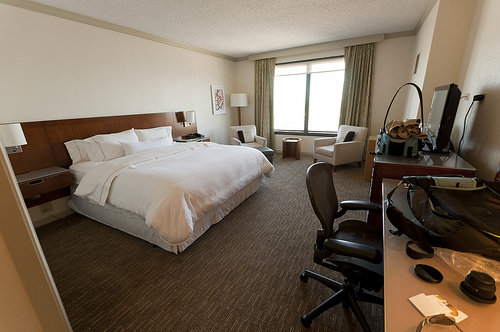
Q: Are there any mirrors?
A: No, there are no mirrors.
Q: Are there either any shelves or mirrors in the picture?
A: No, there are no mirrors or shelves.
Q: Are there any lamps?
A: Yes, there is a lamp.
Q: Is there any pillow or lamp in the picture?
A: Yes, there is a lamp.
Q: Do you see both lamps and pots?
A: No, there is a lamp but no pots.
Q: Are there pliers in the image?
A: No, there are no pliers.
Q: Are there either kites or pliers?
A: No, there are no pliers or kites.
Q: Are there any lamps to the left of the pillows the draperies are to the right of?
A: Yes, there is a lamp to the left of the pillows.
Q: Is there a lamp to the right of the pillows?
A: No, the lamp is to the left of the pillows.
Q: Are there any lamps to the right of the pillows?
A: No, the lamp is to the left of the pillows.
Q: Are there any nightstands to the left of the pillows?
A: No, there is a lamp to the left of the pillows.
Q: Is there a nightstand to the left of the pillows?
A: No, there is a lamp to the left of the pillows.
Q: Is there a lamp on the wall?
A: Yes, there is a lamp on the wall.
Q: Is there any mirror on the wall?
A: No, there is a lamp on the wall.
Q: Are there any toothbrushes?
A: No, there are no toothbrushes.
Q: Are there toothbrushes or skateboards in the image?
A: No, there are no toothbrushes or skateboards.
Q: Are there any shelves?
A: No, there are no shelves.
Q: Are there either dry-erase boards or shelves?
A: No, there are no shelves or dry-erase boards.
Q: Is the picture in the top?
A: Yes, the picture is in the top of the image.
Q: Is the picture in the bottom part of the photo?
A: No, the picture is in the top of the image.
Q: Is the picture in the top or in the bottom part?
A: The picture is in the top of the image.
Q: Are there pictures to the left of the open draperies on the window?
A: Yes, there is a picture to the left of the drapes.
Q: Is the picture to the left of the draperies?
A: Yes, the picture is to the left of the draperies.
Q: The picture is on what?
A: The picture is on the wall.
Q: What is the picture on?
A: The picture is on the wall.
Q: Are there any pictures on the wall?
A: Yes, there is a picture on the wall.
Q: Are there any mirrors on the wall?
A: No, there is a picture on the wall.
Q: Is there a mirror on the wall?
A: No, there is a picture on the wall.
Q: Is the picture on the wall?
A: Yes, the picture is on the wall.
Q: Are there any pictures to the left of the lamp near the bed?
A: Yes, there is a picture to the left of the lamp.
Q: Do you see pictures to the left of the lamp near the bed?
A: Yes, there is a picture to the left of the lamp.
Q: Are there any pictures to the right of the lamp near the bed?
A: No, the picture is to the left of the lamp.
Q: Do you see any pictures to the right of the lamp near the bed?
A: No, the picture is to the left of the lamp.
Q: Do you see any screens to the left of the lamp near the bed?
A: No, there is a picture to the left of the lamp.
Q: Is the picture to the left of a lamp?
A: Yes, the picture is to the left of a lamp.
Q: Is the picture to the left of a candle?
A: No, the picture is to the left of a lamp.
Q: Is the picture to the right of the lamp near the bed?
A: No, the picture is to the left of the lamp.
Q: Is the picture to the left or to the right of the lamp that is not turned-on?
A: The picture is to the left of the lamp.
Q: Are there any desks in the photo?
A: Yes, there is a desk.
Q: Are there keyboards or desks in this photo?
A: Yes, there is a desk.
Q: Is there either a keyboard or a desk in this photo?
A: Yes, there is a desk.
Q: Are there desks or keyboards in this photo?
A: Yes, there is a desk.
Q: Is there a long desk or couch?
A: Yes, there is a long desk.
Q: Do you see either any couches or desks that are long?
A: Yes, the desk is long.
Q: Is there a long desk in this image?
A: Yes, there is a long desk.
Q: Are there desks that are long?
A: Yes, there is a desk that is long.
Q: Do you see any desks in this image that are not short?
A: Yes, there is a long desk.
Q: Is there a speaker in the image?
A: No, there are no speakers.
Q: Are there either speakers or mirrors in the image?
A: No, there are no speakers or mirrors.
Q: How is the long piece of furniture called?
A: The piece of furniture is a desk.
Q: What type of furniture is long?
A: The furniture is a desk.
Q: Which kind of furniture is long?
A: The furniture is a desk.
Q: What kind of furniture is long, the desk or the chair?
A: The desk is long.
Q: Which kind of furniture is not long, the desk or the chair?
A: The chair is not long.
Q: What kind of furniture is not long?
A: The furniture is a chair.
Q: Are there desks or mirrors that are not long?
A: No, there is a desk but it is long.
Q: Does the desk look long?
A: Yes, the desk is long.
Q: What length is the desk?
A: The desk is long.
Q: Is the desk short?
A: No, the desk is long.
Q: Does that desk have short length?
A: No, the desk is long.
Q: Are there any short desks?
A: No, there is a desk but it is long.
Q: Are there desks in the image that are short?
A: No, there is a desk but it is long.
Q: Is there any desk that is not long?
A: No, there is a desk but it is long.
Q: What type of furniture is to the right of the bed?
A: The piece of furniture is a desk.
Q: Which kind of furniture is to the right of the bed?
A: The piece of furniture is a desk.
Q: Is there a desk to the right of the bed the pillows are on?
A: Yes, there is a desk to the right of the bed.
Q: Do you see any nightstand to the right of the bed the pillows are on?
A: No, there is a desk to the right of the bed.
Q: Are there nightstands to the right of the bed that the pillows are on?
A: No, there is a desk to the right of the bed.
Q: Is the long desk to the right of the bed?
A: Yes, the desk is to the right of the bed.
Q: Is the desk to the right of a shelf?
A: No, the desk is to the right of the bed.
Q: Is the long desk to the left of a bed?
A: No, the desk is to the right of a bed.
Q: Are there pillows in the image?
A: Yes, there are pillows.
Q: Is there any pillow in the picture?
A: Yes, there are pillows.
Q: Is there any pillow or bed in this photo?
A: Yes, there are pillows.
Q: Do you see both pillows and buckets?
A: No, there are pillows but no buckets.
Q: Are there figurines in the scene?
A: No, there are no figurines.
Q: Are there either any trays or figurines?
A: No, there are no figurines or trays.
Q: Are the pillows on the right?
A: No, the pillows are on the left of the image.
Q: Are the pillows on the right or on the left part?
A: The pillows are on the left of the image.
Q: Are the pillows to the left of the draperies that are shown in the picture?
A: Yes, the pillows are to the left of the draperies.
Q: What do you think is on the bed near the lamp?
A: The pillows are on the bed.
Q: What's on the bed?
A: The pillows are on the bed.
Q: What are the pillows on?
A: The pillows are on the bed.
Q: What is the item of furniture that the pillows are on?
A: The piece of furniture is a bed.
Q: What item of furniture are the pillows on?
A: The pillows are on the bed.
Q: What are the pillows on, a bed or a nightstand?
A: The pillows are on a bed.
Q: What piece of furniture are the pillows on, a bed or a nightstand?
A: The pillows are on a bed.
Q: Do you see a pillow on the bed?
A: Yes, there are pillows on the bed.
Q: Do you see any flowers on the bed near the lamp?
A: No, there are pillows on the bed.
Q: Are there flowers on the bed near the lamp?
A: No, there are pillows on the bed.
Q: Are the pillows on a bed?
A: Yes, the pillows are on a bed.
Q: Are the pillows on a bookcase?
A: No, the pillows are on a bed.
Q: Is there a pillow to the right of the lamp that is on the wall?
A: Yes, there are pillows to the right of the lamp.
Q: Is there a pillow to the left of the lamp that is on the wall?
A: No, the pillows are to the right of the lamp.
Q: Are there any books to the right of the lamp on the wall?
A: No, there are pillows to the right of the lamp.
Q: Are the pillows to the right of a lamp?
A: Yes, the pillows are to the right of a lamp.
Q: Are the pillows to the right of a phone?
A: No, the pillows are to the right of a lamp.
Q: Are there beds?
A: Yes, there is a bed.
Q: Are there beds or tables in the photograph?
A: Yes, there is a bed.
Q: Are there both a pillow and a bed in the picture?
A: Yes, there are both a bed and a pillow.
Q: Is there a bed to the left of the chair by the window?
A: Yes, there is a bed to the left of the chair.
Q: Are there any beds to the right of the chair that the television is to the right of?
A: No, the bed is to the left of the chair.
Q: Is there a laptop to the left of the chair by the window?
A: No, there is a bed to the left of the chair.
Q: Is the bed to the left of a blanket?
A: No, the bed is to the left of the chair.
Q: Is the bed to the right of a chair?
A: No, the bed is to the left of a chair.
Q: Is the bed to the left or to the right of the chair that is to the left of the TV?
A: The bed is to the left of the chair.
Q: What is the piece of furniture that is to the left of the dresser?
A: The piece of furniture is a bed.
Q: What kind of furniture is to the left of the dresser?
A: The piece of furniture is a bed.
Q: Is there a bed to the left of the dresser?
A: Yes, there is a bed to the left of the dresser.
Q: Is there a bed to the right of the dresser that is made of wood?
A: No, the bed is to the left of the dresser.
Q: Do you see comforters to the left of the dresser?
A: No, there is a bed to the left of the dresser.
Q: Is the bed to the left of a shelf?
A: No, the bed is to the left of a dresser.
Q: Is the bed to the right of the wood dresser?
A: No, the bed is to the left of the dresser.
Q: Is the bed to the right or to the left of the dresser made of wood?
A: The bed is to the left of the dresser.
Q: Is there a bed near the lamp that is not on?
A: Yes, there is a bed near the lamp.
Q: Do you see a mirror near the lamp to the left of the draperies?
A: No, there is a bed near the lamp.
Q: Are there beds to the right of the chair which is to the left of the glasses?
A: No, the bed is to the left of the chair.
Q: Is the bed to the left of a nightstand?
A: No, the bed is to the left of the chair.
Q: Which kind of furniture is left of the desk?
A: The piece of furniture is a bed.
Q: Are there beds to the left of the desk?
A: Yes, there is a bed to the left of the desk.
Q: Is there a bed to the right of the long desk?
A: No, the bed is to the left of the desk.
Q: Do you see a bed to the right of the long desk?
A: No, the bed is to the left of the desk.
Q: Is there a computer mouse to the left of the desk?
A: No, there is a bed to the left of the desk.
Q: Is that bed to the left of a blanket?
A: No, the bed is to the left of the desk.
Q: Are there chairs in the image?
A: Yes, there is a chair.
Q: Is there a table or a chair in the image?
A: Yes, there is a chair.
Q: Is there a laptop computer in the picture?
A: No, there are no laptops.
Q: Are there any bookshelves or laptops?
A: No, there are no laptops or bookshelves.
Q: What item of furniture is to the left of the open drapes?
A: The piece of furniture is a chair.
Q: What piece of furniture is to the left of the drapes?
A: The piece of furniture is a chair.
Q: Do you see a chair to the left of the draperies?
A: Yes, there is a chair to the left of the draperies.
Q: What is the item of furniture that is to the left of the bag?
A: The piece of furniture is a chair.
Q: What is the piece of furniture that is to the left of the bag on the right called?
A: The piece of furniture is a chair.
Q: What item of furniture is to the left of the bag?
A: The piece of furniture is a chair.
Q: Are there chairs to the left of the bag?
A: Yes, there is a chair to the left of the bag.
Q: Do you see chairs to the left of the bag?
A: Yes, there is a chair to the left of the bag.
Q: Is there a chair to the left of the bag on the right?
A: Yes, there is a chair to the left of the bag.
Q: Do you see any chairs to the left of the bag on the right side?
A: Yes, there is a chair to the left of the bag.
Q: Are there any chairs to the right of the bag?
A: No, the chair is to the left of the bag.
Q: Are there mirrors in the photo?
A: No, there are no mirrors.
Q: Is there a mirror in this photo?
A: No, there are no mirrors.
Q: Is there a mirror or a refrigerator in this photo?
A: No, there are no mirrors or refrigerators.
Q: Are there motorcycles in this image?
A: No, there are no motorcycles.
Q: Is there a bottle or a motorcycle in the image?
A: No, there are no motorcycles or bottles.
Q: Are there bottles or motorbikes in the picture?
A: No, there are no motorbikes or bottles.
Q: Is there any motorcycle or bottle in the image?
A: No, there are no motorcycles or bottles.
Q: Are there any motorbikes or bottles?
A: No, there are no motorbikes or bottles.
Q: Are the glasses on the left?
A: No, the glasses are on the right of the image.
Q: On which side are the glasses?
A: The glasses are on the right of the image.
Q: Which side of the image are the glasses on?
A: The glasses are on the right of the image.